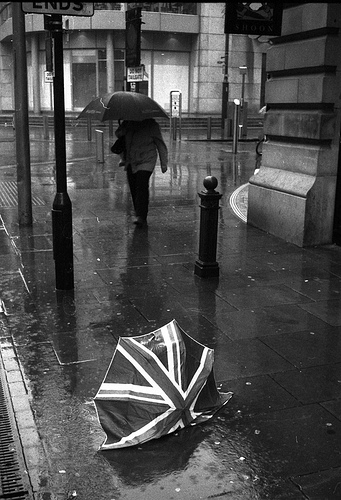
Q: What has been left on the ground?
A: Umbrella.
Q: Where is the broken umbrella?
A: Sidewalk.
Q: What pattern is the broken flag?
A: Union Jack flag.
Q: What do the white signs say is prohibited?
A: Tailgating.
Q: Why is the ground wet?
A: It's raining.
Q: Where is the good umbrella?
A: Person's hand.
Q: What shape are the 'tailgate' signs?
A: Rectangle.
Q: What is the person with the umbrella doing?
A: Walking.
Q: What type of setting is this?
A: Urban.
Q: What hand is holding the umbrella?
A: Right.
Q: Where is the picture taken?
A: A sidewalk.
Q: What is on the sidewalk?
A: An umbrella.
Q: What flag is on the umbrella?
A: The Union Jack.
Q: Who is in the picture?
A: A woman.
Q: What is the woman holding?
A: An umbrella.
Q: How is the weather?
A: Rainy.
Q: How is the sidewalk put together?
A: With pavers.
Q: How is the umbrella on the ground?
A: Broken.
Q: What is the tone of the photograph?
A: It is black and white.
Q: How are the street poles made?
A: Of iron.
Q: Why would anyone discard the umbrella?
A: Broken.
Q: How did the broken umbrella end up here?
A: Useless to owner.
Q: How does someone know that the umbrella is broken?
A: Lying on broken spokes.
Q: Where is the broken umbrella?
A: Rainy pavement.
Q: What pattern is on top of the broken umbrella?
A: Bold white stripes.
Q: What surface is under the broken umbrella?
A: Concrete.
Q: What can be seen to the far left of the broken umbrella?
A: Sewer grate.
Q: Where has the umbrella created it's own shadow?
A: Broken side.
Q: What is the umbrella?
A: Broken.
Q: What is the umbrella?
A: Broken.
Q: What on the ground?
A: Umbrella.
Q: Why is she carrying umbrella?
A: Raining.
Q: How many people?
A: 1.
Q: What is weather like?
A: Raining.